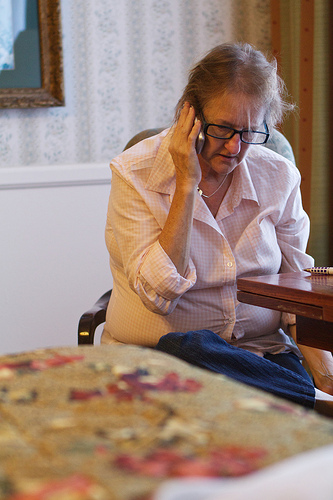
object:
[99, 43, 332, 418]
woman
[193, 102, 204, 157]
phone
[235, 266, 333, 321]
table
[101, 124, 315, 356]
shirt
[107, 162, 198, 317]
sleeve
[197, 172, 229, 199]
jewelry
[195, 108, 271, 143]
glasses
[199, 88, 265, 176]
face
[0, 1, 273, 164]
wallpaper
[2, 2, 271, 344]
wall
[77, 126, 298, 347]
chair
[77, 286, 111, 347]
arm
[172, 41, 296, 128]
hair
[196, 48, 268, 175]
head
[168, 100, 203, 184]
hand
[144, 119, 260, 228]
collar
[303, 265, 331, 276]
fountain pen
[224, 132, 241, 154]
nose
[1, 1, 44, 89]
picture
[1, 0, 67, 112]
frame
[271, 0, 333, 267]
curtain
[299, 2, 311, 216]
stripe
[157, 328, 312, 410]
pants